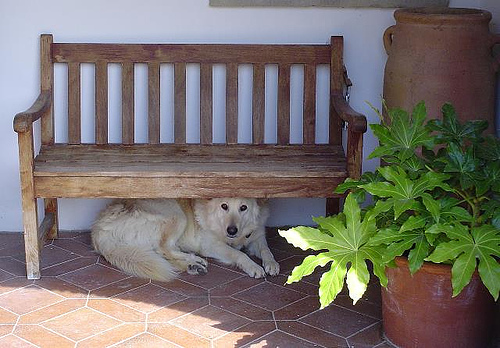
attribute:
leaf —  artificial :
[345, 257, 369, 304]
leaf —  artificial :
[405, 238, 428, 275]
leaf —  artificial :
[447, 252, 478, 298]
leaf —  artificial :
[310, 210, 347, 237]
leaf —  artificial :
[376, 162, 404, 185]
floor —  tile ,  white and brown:
[41, 292, 107, 341]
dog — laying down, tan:
[103, 174, 290, 287]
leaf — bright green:
[349, 157, 473, 257]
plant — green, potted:
[366, 175, 478, 338]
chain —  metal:
[341, 81, 357, 127]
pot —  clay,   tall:
[381, 7, 499, 167]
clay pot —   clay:
[380, 9, 497, 161]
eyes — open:
[219, 201, 249, 214]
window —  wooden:
[207, 0, 463, 23]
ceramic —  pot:
[341, 233, 497, 338]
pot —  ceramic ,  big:
[368, 12, 490, 149]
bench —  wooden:
[120, 76, 292, 156]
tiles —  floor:
[198, 309, 329, 342]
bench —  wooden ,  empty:
[14, 34, 367, 279]